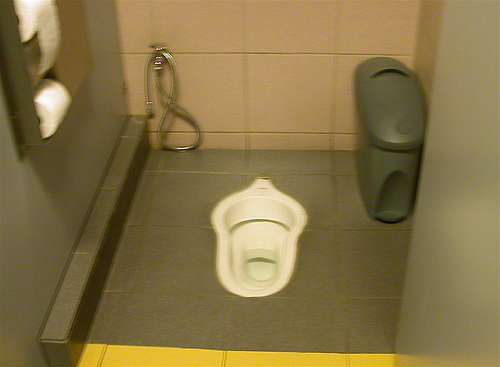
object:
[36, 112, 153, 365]
baseboard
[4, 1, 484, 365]
toilet stall